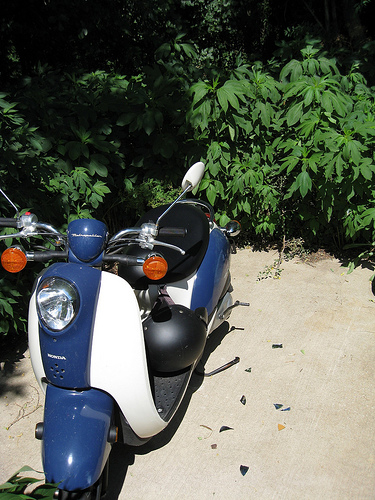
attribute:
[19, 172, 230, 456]
bike — parked, blue, standing, red, black, orange, small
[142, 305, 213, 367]
helmet — black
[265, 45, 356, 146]
trees — green, bushy, dark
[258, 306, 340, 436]
road — paved